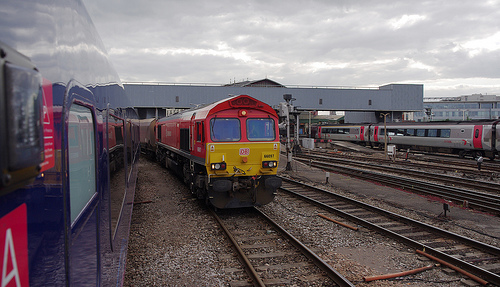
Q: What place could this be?
A: It is a station.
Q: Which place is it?
A: It is a station.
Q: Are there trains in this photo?
A: Yes, there is a train.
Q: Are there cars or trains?
A: Yes, there is a train.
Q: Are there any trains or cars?
A: Yes, there is a train.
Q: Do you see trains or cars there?
A: Yes, there is a train.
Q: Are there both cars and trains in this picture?
A: Yes, there are both a train and a car.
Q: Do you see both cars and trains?
A: Yes, there are both a train and a car.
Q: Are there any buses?
A: No, there are no buses.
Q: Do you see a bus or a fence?
A: No, there are no buses or fences.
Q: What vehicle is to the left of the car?
A: The vehicle is a train.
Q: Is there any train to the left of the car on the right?
A: Yes, there is a train to the left of the car.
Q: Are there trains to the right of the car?
A: No, the train is to the left of the car.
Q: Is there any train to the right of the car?
A: No, the train is to the left of the car.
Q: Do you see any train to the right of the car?
A: No, the train is to the left of the car.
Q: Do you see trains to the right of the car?
A: No, the train is to the left of the car.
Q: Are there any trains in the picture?
A: Yes, there is a train.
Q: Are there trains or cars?
A: Yes, there is a train.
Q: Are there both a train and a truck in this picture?
A: No, there is a train but no trucks.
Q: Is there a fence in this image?
A: No, there are no fences.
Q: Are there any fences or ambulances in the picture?
A: No, there are no fences or ambulances.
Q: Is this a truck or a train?
A: This is a train.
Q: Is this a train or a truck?
A: This is a train.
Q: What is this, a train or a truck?
A: This is a train.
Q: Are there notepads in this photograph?
A: No, there are no notepads.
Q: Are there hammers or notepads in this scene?
A: No, there are no notepads or hammers.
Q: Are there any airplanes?
A: No, there are no airplanes.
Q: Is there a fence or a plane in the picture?
A: No, there are no airplanes or fences.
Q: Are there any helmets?
A: No, there are no helmets.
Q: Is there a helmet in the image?
A: No, there are no helmets.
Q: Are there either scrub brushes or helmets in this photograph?
A: No, there are no helmets or scrub brushes.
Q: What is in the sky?
A: The clouds are in the sky.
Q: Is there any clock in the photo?
A: No, there are no clocks.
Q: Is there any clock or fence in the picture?
A: No, there are no clocks or fences.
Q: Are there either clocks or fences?
A: No, there are no clocks or fences.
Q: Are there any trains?
A: Yes, there is a train.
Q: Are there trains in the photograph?
A: Yes, there is a train.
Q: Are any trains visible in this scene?
A: Yes, there is a train.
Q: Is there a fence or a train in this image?
A: Yes, there is a train.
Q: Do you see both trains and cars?
A: Yes, there are both a train and a car.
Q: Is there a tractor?
A: No, there are no tractors.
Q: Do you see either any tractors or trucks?
A: No, there are no tractors or trucks.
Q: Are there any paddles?
A: No, there are no paddles.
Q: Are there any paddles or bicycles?
A: No, there are no paddles or bicycles.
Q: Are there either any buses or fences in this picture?
A: No, there are no buses or fences.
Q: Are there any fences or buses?
A: No, there are no buses or fences.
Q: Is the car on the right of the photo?
A: Yes, the car is on the right of the image.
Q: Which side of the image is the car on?
A: The car is on the right of the image.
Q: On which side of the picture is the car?
A: The car is on the right of the image.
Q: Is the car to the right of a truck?
A: No, the car is to the right of a train.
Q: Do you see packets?
A: No, there are no packets.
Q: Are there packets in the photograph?
A: No, there are no packets.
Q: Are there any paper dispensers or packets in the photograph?
A: No, there are no packets or paper dispensers.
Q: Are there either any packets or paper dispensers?
A: No, there are no packets or paper dispensers.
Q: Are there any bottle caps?
A: No, there are no bottle caps.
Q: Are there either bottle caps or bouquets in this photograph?
A: No, there are no bottle caps or bouquets.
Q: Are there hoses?
A: No, there are no hoses.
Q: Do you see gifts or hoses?
A: No, there are no hoses or gifts.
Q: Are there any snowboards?
A: No, there are no snowboards.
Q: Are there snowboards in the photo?
A: No, there are no snowboards.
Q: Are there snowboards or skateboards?
A: No, there are no snowboards or skateboards.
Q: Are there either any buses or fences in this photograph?
A: No, there are no buses or fences.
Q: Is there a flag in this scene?
A: No, there are no flags.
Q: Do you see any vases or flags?
A: No, there are no flags or vases.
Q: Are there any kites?
A: No, there are no kites.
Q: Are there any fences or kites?
A: No, there are no kites or fences.